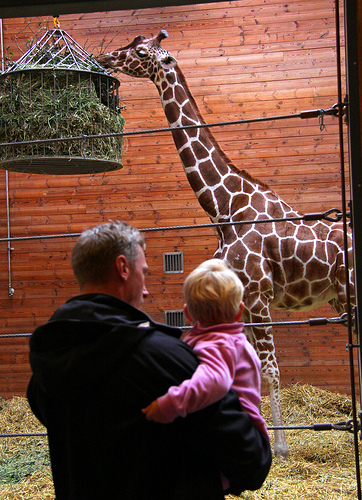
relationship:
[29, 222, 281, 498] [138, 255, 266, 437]
man looking at baby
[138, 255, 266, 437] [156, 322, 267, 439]
baby wearing sweater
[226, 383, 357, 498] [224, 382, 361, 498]
hay in ground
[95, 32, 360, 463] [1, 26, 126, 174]
giraffe eating from basket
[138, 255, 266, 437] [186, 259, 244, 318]
baby has hair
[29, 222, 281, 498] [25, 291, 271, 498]
man wearing jacket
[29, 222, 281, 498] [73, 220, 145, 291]
man has hair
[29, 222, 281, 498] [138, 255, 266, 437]
man holding baby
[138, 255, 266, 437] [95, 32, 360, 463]
baby looking at giraffe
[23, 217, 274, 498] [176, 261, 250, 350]
man holding baby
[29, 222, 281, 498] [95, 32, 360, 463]
man looking giraffe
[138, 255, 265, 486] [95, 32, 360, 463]
baby looking giraffe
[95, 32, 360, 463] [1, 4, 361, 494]
giraffe in pin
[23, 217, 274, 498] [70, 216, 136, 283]
man with hair